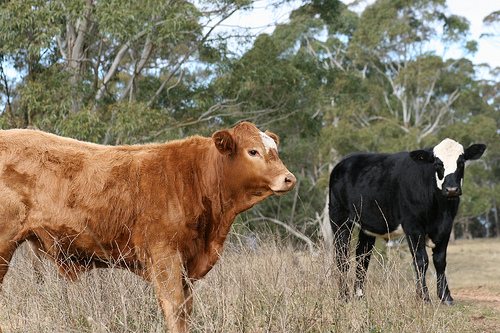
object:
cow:
[327, 138, 487, 305]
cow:
[1, 121, 298, 331]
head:
[411, 137, 487, 200]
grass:
[0, 193, 450, 331]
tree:
[1, 0, 318, 145]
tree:
[272, 1, 364, 246]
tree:
[328, 0, 499, 247]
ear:
[410, 149, 435, 165]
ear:
[465, 143, 487, 161]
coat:
[327, 138, 486, 306]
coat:
[1, 121, 298, 331]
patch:
[433, 138, 465, 190]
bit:
[188, 188, 273, 281]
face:
[231, 121, 297, 196]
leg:
[404, 226, 431, 302]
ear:
[212, 130, 236, 155]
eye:
[249, 149, 260, 155]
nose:
[444, 185, 460, 196]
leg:
[432, 230, 456, 305]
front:
[405, 139, 488, 305]